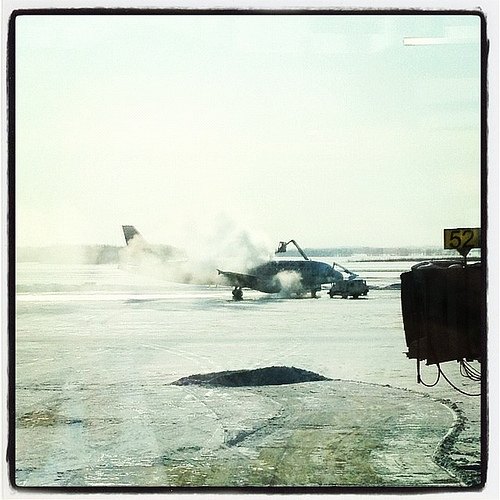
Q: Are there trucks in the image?
A: Yes, there is a truck.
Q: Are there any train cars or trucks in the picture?
A: Yes, there is a truck.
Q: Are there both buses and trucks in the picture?
A: No, there is a truck but no buses.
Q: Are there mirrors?
A: No, there are no mirrors.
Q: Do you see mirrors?
A: No, there are no mirrors.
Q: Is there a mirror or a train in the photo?
A: No, there are no mirrors or trains.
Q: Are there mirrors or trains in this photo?
A: No, there are no mirrors or trains.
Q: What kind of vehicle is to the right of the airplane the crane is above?
A: The vehicle is a truck.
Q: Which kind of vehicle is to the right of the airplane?
A: The vehicle is a truck.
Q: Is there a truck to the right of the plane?
A: Yes, there is a truck to the right of the plane.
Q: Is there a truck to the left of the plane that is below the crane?
A: No, the truck is to the right of the plane.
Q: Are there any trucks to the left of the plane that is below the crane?
A: No, the truck is to the right of the plane.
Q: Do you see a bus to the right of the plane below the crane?
A: No, there is a truck to the right of the airplane.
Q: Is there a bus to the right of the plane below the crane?
A: No, there is a truck to the right of the airplane.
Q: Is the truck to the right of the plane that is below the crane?
A: Yes, the truck is to the right of the airplane.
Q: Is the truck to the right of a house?
A: No, the truck is to the right of the airplane.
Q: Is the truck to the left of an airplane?
A: No, the truck is to the right of an airplane.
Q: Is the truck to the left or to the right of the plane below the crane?
A: The truck is to the right of the airplane.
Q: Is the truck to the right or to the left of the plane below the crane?
A: The truck is to the right of the airplane.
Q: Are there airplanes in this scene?
A: Yes, there is an airplane.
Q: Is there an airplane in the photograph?
A: Yes, there is an airplane.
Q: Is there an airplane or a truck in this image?
A: Yes, there is an airplane.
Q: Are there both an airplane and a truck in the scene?
A: Yes, there are both an airplane and a truck.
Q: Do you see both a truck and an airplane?
A: Yes, there are both an airplane and a truck.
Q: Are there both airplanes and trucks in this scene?
A: Yes, there are both an airplane and a truck.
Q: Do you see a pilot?
A: No, there are no pilots.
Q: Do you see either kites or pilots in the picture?
A: No, there are no pilots or kites.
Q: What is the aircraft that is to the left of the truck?
A: The aircraft is an airplane.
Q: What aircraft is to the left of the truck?
A: The aircraft is an airplane.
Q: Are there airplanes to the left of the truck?
A: Yes, there is an airplane to the left of the truck.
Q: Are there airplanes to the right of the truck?
A: No, the airplane is to the left of the truck.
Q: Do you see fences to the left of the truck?
A: No, there is an airplane to the left of the truck.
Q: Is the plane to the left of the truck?
A: Yes, the plane is to the left of the truck.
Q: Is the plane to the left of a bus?
A: No, the plane is to the left of the truck.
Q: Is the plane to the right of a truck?
A: No, the plane is to the left of a truck.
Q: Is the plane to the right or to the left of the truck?
A: The plane is to the left of the truck.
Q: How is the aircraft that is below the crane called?
A: The aircraft is an airplane.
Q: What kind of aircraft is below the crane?
A: The aircraft is an airplane.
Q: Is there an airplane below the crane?
A: Yes, there is an airplane below the crane.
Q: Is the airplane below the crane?
A: Yes, the airplane is below the crane.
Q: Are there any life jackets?
A: No, there are no life jackets.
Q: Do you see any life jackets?
A: No, there are no life jackets.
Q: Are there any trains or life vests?
A: No, there are no life vests or trains.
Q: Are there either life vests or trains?
A: No, there are no life vests or trains.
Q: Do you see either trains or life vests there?
A: No, there are no life vests or trains.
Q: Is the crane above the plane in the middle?
A: Yes, the crane is above the plane.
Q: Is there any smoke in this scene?
A: Yes, there is smoke.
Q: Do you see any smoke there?
A: Yes, there is smoke.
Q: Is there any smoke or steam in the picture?
A: Yes, there is smoke.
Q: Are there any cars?
A: No, there are no cars.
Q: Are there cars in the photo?
A: No, there are no cars.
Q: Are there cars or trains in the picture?
A: No, there are no cars or trains.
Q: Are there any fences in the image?
A: No, there are no fences.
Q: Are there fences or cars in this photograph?
A: No, there are no fences or cars.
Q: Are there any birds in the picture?
A: No, there are no birds.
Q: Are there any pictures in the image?
A: No, there are no pictures.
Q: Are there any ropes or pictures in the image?
A: No, there are no pictures or ropes.